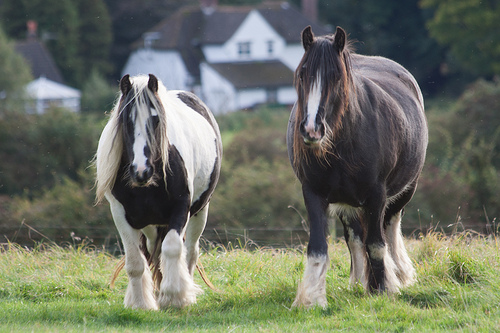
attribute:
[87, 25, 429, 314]
two horses — black, white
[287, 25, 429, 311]
horse — brown, big, black, white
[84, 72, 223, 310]
horse — brown, white, black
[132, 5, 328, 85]
roof — brown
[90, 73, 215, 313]
fur — white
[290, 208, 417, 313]
fur — white, horse